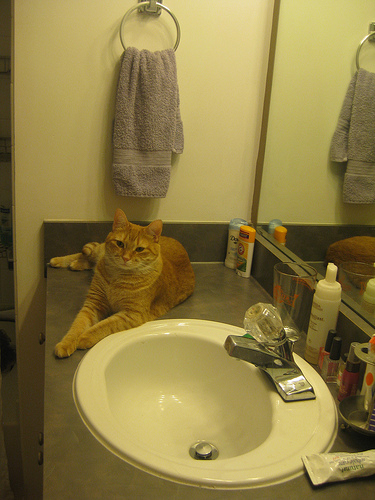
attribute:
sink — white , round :
[72, 318, 339, 491]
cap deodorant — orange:
[234, 220, 262, 243]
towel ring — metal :
[118, 2, 181, 57]